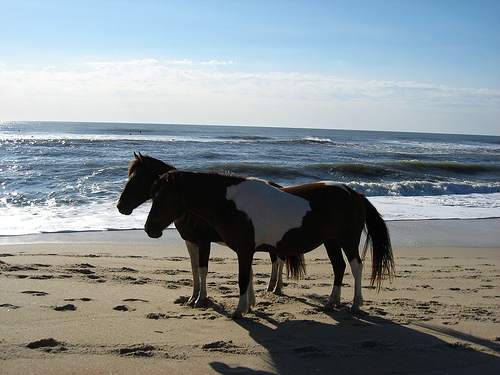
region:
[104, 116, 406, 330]
two horses standing onthe beach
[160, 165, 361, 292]
the brown and white horse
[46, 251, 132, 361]
the sand on the beach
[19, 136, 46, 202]
the waves in the water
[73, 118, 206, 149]
the horizon of the scene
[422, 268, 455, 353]
foot prints in the sand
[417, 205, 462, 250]
the water meets the sand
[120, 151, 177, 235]
the faces of the horses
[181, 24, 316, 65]
the blue sky in the photo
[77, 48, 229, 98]
the few clouds in the photo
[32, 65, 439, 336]
horses on the beach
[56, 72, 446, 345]
some horses on the beach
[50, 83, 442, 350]
beautiful horses on the beach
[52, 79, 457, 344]
two horses on the beach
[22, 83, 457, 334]
couple horses on the beach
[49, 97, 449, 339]
elegant horses on the beach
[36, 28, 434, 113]
patch of blue sky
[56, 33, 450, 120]
patch of sky with clouds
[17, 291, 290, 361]
prints in the sand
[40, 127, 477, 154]
some calm ocean waves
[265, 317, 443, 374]
the shadow is black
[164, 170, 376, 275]
the horse is brown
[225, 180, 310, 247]
the spot is white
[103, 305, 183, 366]
there are foot prints on ground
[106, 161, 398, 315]
the horses are two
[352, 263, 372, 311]
the end of leg is white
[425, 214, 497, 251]
the beach is wet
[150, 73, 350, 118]
the sky has less clouds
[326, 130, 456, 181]
there are small waves in the ocean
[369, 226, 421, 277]
the tail is black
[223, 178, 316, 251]
White spot on a horse's body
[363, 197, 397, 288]
Brown tail of a horse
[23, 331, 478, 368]
Footprints in the sand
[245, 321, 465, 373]
Shadows of two horses in the sand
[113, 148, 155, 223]
Head of a horse facing left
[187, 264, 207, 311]
White hooves of a horse in the sand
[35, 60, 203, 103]
Clouds in the sky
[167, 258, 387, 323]
Eight horse hooves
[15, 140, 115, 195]
Blue ocean water behind horses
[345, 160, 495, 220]
Waves approaching a beach